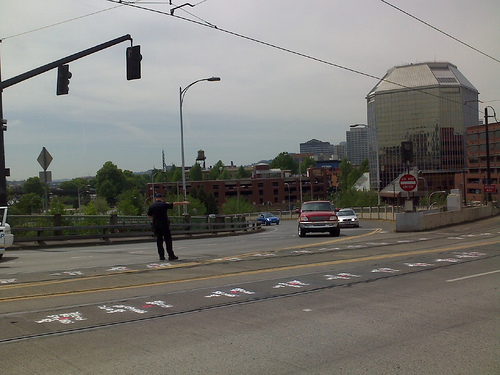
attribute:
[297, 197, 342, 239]
truck — red